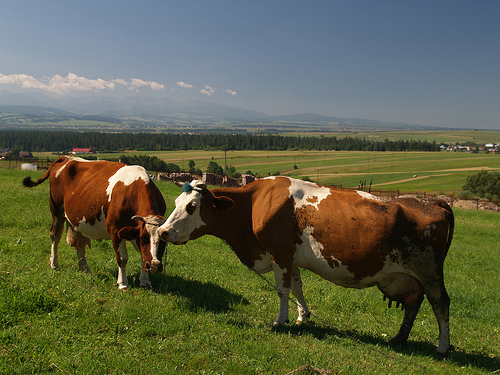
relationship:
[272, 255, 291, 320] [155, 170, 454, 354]
leg of cow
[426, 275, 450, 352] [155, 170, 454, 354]
leg of cow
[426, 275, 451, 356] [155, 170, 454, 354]
leg of cow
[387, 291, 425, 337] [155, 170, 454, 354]
leg of cow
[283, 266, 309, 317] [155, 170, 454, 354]
leg of cow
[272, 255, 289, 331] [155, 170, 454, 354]
leg of cow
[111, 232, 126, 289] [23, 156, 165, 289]
leg of cow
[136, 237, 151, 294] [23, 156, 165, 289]
leg of cow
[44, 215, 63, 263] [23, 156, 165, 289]
leg of cow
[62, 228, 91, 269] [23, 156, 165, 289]
leg of cow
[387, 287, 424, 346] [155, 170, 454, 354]
leg of cow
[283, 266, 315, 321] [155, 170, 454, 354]
leg of cow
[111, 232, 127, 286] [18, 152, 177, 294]
leg of cow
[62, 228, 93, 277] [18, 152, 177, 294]
leg of cow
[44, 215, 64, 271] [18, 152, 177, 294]
leg of cow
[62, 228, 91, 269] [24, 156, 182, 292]
leg of cow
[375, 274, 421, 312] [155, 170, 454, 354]
udder of cow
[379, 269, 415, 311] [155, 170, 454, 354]
udder of cow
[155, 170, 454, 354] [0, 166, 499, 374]
cow in grass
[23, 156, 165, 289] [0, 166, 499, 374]
cow in grass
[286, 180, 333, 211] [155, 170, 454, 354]
spots on cow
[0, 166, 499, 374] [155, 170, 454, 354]
grass under cow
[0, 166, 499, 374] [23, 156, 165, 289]
grass under cow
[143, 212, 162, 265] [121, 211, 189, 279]
streak on face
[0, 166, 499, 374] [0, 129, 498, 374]
grass on ground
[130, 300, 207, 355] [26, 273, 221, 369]
grass on ground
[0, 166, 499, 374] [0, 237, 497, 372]
grass on ground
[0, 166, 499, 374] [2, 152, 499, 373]
grass on ground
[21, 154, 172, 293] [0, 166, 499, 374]
cow in grass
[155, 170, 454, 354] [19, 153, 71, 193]
cow has tail